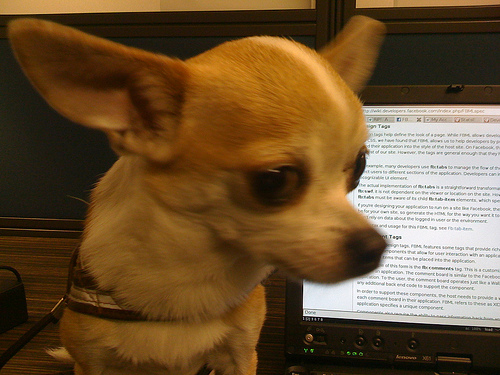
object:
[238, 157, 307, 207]
eye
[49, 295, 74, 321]
silver spot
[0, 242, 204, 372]
leash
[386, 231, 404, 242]
words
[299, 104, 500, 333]
laptop screen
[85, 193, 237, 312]
white fur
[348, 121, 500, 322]
writing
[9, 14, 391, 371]
dog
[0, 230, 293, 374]
table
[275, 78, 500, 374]
laptop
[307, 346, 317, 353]
lights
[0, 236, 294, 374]
surface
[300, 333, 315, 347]
button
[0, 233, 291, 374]
floor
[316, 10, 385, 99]
ear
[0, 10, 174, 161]
ear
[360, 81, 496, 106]
top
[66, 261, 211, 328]
collar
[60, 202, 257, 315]
neck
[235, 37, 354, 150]
stripe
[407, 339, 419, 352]
button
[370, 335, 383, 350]
button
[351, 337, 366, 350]
button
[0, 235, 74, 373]
carpet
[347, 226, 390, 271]
nose